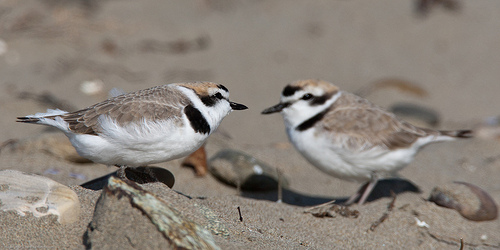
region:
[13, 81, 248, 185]
Bird is white and black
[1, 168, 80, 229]
Rock is round and white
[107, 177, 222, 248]
leaf is green and brown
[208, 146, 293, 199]
rock is small and dark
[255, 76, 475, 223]
Bird is white and brown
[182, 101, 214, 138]
marking on bird is black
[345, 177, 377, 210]
bird has thin legs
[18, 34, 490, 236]
2 birds looking at each other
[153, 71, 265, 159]
small bird with black markings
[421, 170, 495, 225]
rock behind the bird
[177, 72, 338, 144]
birds beaks near each other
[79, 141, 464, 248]
bird's feet in the sand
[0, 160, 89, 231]
Rock sits behind the bird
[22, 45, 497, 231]
2 birds look almost identical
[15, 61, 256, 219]
a small black beaked bird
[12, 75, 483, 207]
two birds playing with each other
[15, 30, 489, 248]
a bunch of rocks on some sand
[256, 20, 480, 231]
a bird standing on a sandy beach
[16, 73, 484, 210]
a small bird looking at a brd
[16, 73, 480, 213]
a small group of birds look at each other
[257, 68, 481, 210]
a little gray winged bird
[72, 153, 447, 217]
teh shadows of birds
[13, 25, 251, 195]
a bird walking across rocky sand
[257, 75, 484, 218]
blurry image of a bird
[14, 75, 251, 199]
clear image of a bird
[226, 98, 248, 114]
black beak of bird on left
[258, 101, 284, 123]
beak of bird on right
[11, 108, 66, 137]
tail feathers of bird on left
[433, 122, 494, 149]
tail feathers of bird on right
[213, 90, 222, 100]
right eye of a bird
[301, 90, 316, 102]
left eye of a bird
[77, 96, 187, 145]
right wing of a bird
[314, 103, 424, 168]
left wing of a bird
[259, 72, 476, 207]
A small bird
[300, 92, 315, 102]
black eye of small bird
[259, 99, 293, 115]
Black beak of bird